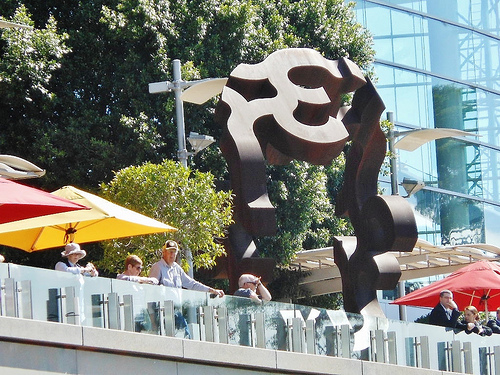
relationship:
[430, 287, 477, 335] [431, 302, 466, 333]
man wearing suit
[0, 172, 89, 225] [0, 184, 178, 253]
umbrella next to umbrella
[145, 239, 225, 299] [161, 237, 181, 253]
man wearing ball cap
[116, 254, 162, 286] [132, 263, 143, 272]
woman wearing sunglasses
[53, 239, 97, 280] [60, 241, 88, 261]
woman wearing sun hat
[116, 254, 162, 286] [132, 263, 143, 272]
woman has sunglasses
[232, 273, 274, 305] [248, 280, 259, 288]
man wearing sunglasses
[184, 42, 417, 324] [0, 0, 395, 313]
sculpture in front of trees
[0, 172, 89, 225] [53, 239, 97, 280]
umbrella behind woman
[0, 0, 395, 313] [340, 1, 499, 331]
trees next to building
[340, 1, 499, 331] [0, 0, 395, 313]
building next to trees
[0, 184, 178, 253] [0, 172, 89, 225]
umbrella next to umbrella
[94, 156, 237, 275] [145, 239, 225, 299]
tree behind man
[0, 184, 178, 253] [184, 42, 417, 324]
umbrella near sculpture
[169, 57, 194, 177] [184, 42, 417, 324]
light pole near sculpture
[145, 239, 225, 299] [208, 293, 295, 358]
man holding panel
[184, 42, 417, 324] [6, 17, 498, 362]
sculpture in plaza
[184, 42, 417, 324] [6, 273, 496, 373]
sculpture on street